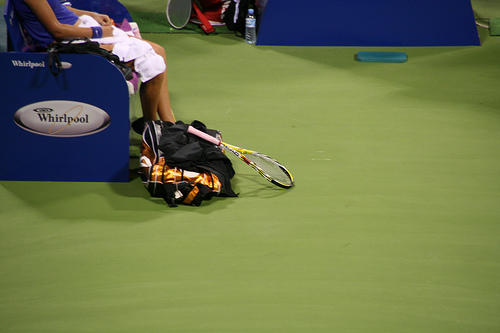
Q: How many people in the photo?
A: One.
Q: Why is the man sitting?
A: To rest.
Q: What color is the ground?
A: Green.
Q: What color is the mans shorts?
A: White.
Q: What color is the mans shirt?
A: Blue.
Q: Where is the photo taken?
A: Tennis court.